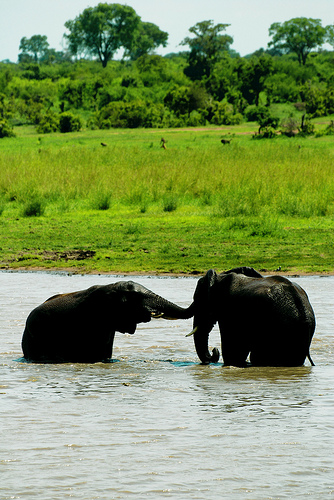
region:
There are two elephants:
[29, 258, 332, 389]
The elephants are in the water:
[45, 287, 330, 381]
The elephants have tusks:
[120, 271, 231, 373]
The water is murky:
[52, 370, 317, 498]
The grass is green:
[117, 181, 282, 276]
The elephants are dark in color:
[229, 283, 321, 401]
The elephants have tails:
[267, 324, 328, 380]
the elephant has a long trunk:
[186, 332, 276, 399]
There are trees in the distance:
[76, 15, 302, 158]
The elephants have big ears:
[34, 280, 259, 435]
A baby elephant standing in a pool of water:
[18, 271, 194, 366]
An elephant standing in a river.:
[186, 250, 323, 369]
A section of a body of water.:
[188, 409, 287, 462]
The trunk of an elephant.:
[189, 319, 218, 373]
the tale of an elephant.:
[289, 292, 324, 371]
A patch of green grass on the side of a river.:
[199, 167, 279, 221]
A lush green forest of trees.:
[140, 56, 255, 150]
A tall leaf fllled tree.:
[57, 6, 168, 86]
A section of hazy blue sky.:
[240, 12, 257, 26]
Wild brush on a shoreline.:
[232, 113, 313, 143]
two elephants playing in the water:
[42, 223, 309, 461]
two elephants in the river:
[55, 274, 326, 490]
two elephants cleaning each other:
[20, 251, 329, 480]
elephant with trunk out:
[39, 238, 177, 435]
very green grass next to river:
[61, 89, 327, 415]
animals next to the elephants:
[74, 27, 333, 225]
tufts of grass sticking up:
[50, 140, 285, 368]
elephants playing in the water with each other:
[82, 229, 307, 448]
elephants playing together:
[41, 211, 302, 499]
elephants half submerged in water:
[50, 239, 305, 486]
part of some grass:
[255, 166, 289, 193]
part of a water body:
[192, 448, 230, 485]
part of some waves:
[155, 421, 189, 459]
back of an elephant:
[283, 300, 298, 324]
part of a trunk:
[167, 310, 188, 325]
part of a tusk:
[150, 303, 170, 323]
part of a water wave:
[136, 431, 174, 473]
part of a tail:
[298, 331, 314, 356]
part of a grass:
[166, 231, 209, 271]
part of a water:
[143, 436, 195, 478]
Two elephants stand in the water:
[45, 273, 319, 387]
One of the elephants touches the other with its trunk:
[36, 285, 298, 382]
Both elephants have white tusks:
[35, 272, 316, 392]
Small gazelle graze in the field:
[65, 123, 265, 159]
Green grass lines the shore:
[15, 214, 317, 282]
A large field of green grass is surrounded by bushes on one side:
[21, 84, 323, 239]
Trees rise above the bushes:
[19, 7, 318, 83]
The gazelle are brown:
[97, 125, 228, 160]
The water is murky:
[55, 332, 322, 426]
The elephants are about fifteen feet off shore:
[23, 239, 312, 382]